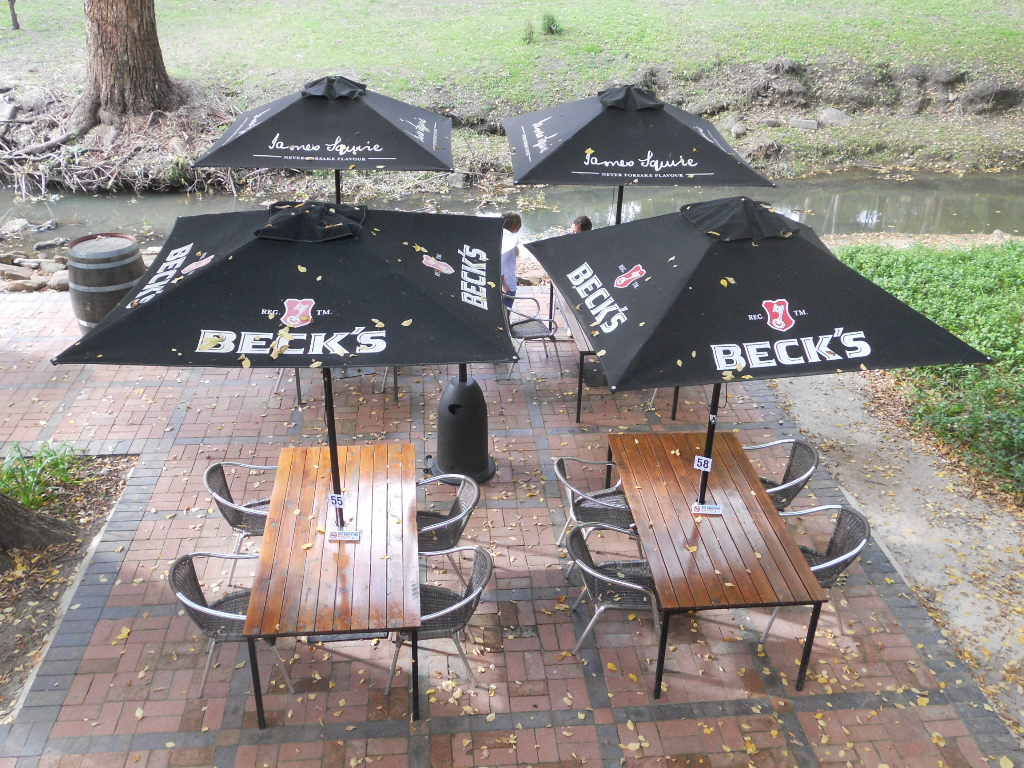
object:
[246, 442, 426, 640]
table top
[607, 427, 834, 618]
table top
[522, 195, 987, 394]
umbrella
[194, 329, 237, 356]
letters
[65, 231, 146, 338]
barrel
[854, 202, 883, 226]
light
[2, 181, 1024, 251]
water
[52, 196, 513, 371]
umbrella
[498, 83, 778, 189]
umbrella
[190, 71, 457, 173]
umbrella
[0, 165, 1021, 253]
creek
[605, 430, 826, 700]
table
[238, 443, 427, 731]
table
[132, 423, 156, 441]
bricks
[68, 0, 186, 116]
tree trunk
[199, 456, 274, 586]
chairs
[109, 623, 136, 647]
leaves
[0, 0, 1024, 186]
ground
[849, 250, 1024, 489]
grass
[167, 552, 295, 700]
chairs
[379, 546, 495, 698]
chairs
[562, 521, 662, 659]
chairs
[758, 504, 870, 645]
chairs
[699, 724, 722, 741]
leaves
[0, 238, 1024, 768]
ground